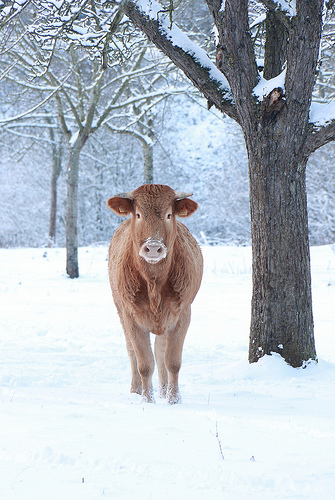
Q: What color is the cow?
A: Brown.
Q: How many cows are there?
A: One.